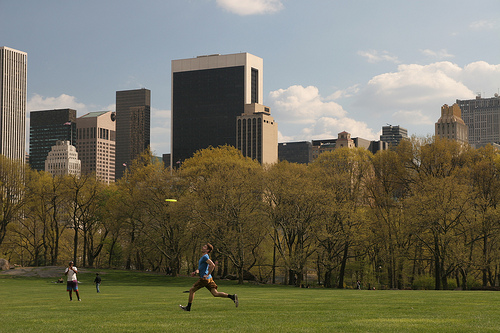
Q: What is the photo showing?
A: It is showing a city.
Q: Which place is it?
A: It is a city.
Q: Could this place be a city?
A: Yes, it is a city.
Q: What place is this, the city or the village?
A: It is the city.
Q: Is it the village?
A: No, it is the city.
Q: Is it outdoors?
A: Yes, it is outdoors.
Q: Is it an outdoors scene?
A: Yes, it is outdoors.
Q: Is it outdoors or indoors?
A: It is outdoors.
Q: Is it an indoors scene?
A: No, it is outdoors.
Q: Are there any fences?
A: No, there are no fences.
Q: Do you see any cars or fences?
A: No, there are no fences or cars.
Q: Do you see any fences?
A: No, there are no fences.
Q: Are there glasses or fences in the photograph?
A: No, there are no fences or glasses.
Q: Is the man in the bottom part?
A: Yes, the man is in the bottom of the image.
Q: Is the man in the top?
A: No, the man is in the bottom of the image.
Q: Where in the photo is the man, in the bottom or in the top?
A: The man is in the bottom of the image.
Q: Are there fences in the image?
A: No, there are no fences.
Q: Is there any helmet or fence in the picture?
A: No, there are no fences or helmets.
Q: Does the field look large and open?
A: Yes, the field is large and open.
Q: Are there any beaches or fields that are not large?
A: No, there is a field but it is large.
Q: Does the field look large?
A: Yes, the field is large.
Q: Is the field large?
A: Yes, the field is large.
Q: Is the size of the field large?
A: Yes, the field is large.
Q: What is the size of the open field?
A: The field is large.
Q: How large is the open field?
A: The field is large.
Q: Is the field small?
A: No, the field is large.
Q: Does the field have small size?
A: No, the field is large.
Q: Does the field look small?
A: No, the field is large.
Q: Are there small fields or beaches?
A: No, there is a field but it is large.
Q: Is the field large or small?
A: The field is large.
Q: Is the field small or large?
A: The field is large.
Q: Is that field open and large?
A: Yes, the field is open and large.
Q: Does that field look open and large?
A: Yes, the field is open and large.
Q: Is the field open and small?
A: No, the field is open but large.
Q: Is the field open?
A: Yes, the field is open.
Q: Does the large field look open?
A: Yes, the field is open.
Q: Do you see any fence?
A: No, there are no fences.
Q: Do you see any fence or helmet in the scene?
A: No, there are no fences or helmets.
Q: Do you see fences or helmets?
A: No, there are no fences or helmets.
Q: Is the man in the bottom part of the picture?
A: Yes, the man is in the bottom of the image.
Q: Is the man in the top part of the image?
A: No, the man is in the bottom of the image.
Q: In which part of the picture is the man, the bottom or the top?
A: The man is in the bottom of the image.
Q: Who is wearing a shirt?
A: The man is wearing a shirt.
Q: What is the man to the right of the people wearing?
A: The man is wearing a shirt.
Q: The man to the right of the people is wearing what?
A: The man is wearing a shirt.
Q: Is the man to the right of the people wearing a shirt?
A: Yes, the man is wearing a shirt.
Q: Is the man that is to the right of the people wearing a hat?
A: No, the man is wearing a shirt.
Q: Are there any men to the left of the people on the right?
A: Yes, there is a man to the left of the people.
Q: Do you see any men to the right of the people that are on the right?
A: No, the man is to the left of the people.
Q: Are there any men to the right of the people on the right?
A: No, the man is to the left of the people.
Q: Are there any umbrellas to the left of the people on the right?
A: No, there is a man to the left of the people.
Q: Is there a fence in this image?
A: No, there are no fences.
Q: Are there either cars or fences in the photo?
A: No, there are no fences or cars.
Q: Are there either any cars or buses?
A: No, there are no cars or buses.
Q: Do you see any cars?
A: No, there are no cars.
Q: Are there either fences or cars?
A: No, there are no cars or fences.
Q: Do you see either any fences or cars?
A: No, there are no fences or cars.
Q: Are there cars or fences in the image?
A: No, there are no fences or cars.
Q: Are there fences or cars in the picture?
A: No, there are no fences or cars.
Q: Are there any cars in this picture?
A: No, there are no cars.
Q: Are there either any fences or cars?
A: No, there are no cars or fences.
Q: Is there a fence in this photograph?
A: No, there are no fences.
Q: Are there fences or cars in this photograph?
A: No, there are no fences or cars.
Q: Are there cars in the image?
A: No, there are no cars.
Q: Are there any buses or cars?
A: No, there are no cars or buses.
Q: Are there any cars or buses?
A: No, there are no cars or buses.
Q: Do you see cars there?
A: No, there are no cars.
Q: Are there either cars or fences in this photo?
A: No, there are no cars or fences.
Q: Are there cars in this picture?
A: No, there are no cars.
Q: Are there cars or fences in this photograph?
A: No, there are no cars or fences.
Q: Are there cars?
A: No, there are no cars.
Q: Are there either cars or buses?
A: No, there are no cars or buses.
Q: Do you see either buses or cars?
A: No, there are no cars or buses.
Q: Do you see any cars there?
A: No, there are no cars.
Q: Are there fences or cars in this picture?
A: No, there are no cars or fences.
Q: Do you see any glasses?
A: No, there are no glasses.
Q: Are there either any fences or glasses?
A: No, there are no glasses or fences.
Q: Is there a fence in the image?
A: No, there are no fences.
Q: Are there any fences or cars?
A: No, there are no fences or cars.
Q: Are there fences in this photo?
A: No, there are no fences.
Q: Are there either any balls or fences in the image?
A: No, there are no fences or balls.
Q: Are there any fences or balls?
A: No, there are no fences or balls.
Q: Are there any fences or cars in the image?
A: No, there are no cars or fences.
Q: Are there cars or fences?
A: No, there are no cars or fences.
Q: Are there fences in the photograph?
A: No, there are no fences.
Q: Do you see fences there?
A: No, there are no fences.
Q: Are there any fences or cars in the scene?
A: No, there are no fences or cars.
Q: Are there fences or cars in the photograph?
A: No, there are no cars or fences.